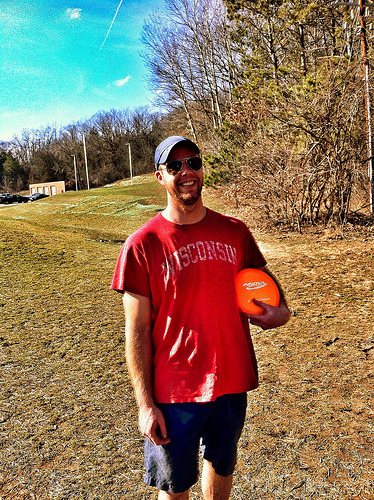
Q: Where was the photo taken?
A: It was taken at the field.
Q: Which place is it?
A: It is a field.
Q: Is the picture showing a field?
A: Yes, it is showing a field.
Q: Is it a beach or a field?
A: It is a field.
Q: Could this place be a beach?
A: No, it is a field.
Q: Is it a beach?
A: No, it is a field.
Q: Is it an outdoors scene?
A: Yes, it is outdoors.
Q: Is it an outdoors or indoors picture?
A: It is outdoors.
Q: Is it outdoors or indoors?
A: It is outdoors.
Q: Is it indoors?
A: No, it is outdoors.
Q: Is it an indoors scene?
A: No, it is outdoors.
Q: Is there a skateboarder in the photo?
A: No, there are no skateboarders.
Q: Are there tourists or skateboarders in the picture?
A: No, there are no skateboarders or tourists.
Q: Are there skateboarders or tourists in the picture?
A: No, there are no skateboarders or tourists.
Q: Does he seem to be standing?
A: Yes, the man is standing.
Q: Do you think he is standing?
A: Yes, the man is standing.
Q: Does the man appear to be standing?
A: Yes, the man is standing.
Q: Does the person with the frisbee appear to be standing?
A: Yes, the man is standing.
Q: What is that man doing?
A: The man is standing.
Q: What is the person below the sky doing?
A: The man is standing.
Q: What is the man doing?
A: The man is standing.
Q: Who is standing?
A: The man is standing.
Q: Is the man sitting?
A: No, the man is standing.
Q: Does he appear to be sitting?
A: No, the man is standing.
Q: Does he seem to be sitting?
A: No, the man is standing.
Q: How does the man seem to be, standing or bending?
A: The man is standing.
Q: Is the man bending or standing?
A: The man is standing.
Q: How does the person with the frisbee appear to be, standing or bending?
A: The man is standing.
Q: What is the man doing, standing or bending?
A: The man is standing.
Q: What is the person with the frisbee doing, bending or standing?
A: The man is standing.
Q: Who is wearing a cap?
A: The man is wearing a cap.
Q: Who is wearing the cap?
A: The man is wearing a cap.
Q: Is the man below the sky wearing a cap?
A: Yes, the man is wearing a cap.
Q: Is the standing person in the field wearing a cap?
A: Yes, the man is wearing a cap.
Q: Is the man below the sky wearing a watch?
A: No, the man is wearing a cap.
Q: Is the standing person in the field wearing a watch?
A: No, the man is wearing a cap.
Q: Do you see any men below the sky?
A: Yes, there is a man below the sky.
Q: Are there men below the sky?
A: Yes, there is a man below the sky.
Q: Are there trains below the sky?
A: No, there is a man below the sky.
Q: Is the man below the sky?
A: Yes, the man is below the sky.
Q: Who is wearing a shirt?
A: The man is wearing a shirt.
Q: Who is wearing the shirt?
A: The man is wearing a shirt.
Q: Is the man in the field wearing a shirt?
A: Yes, the man is wearing a shirt.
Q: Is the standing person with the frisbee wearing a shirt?
A: Yes, the man is wearing a shirt.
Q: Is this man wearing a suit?
A: No, the man is wearing a shirt.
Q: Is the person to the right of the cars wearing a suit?
A: No, the man is wearing a shirt.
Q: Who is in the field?
A: The man is in the field.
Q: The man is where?
A: The man is in the field.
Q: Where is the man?
A: The man is in the field.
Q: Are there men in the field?
A: Yes, there is a man in the field.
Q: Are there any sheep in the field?
A: No, there is a man in the field.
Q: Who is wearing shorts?
A: The man is wearing shorts.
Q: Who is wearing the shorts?
A: The man is wearing shorts.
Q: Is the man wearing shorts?
A: Yes, the man is wearing shorts.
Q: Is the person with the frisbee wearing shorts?
A: Yes, the man is wearing shorts.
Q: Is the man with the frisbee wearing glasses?
A: No, the man is wearing shorts.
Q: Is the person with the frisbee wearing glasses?
A: No, the man is wearing shorts.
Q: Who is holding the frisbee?
A: The man is holding the frisbee.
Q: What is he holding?
A: The man is holding the frisbee.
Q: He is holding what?
A: The man is holding the frisbee.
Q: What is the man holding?
A: The man is holding the frisbee.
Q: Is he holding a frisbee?
A: Yes, the man is holding a frisbee.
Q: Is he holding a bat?
A: No, the man is holding a frisbee.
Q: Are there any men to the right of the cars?
A: Yes, there is a man to the right of the cars.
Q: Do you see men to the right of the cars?
A: Yes, there is a man to the right of the cars.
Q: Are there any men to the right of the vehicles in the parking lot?
A: Yes, there is a man to the right of the cars.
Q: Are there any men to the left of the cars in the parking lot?
A: No, the man is to the right of the cars.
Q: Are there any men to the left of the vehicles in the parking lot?
A: No, the man is to the right of the cars.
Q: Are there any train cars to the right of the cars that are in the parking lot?
A: No, there is a man to the right of the cars.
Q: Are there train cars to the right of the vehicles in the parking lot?
A: No, there is a man to the right of the cars.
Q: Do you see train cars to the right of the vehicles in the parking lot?
A: No, there is a man to the right of the cars.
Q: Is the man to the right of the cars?
A: Yes, the man is to the right of the cars.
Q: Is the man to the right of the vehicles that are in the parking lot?
A: Yes, the man is to the right of the cars.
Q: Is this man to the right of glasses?
A: No, the man is to the right of the cars.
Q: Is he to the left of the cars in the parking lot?
A: No, the man is to the right of the cars.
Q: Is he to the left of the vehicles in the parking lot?
A: No, the man is to the right of the cars.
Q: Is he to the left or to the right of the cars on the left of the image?
A: The man is to the right of the cars.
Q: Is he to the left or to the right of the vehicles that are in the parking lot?
A: The man is to the right of the cars.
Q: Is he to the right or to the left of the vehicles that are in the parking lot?
A: The man is to the right of the cars.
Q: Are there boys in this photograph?
A: No, there are no boys.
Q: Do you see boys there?
A: No, there are no boys.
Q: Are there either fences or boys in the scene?
A: No, there are no boys or fences.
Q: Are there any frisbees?
A: Yes, there is a frisbee.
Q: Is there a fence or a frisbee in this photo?
A: Yes, there is a frisbee.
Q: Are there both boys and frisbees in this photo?
A: No, there is a frisbee but no boys.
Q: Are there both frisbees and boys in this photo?
A: No, there is a frisbee but no boys.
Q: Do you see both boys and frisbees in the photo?
A: No, there is a frisbee but no boys.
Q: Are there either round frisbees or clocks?
A: Yes, there is a round frisbee.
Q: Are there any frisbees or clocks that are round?
A: Yes, the frisbee is round.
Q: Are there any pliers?
A: No, there are no pliers.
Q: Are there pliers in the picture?
A: No, there are no pliers.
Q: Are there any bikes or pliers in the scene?
A: No, there are no pliers or bikes.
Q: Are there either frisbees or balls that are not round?
A: No, there is a frisbee but it is round.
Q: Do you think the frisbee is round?
A: Yes, the frisbee is round.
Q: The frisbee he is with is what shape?
A: The frisbee is round.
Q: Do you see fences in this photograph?
A: No, there are no fences.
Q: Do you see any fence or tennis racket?
A: No, there are no fences or rackets.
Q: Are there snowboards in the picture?
A: No, there are no snowboards.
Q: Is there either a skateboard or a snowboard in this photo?
A: No, there are no snowboards or skateboards.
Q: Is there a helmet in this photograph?
A: No, there are no helmets.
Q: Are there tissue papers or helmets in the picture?
A: No, there are no helmets or tissue papers.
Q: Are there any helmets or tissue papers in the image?
A: No, there are no helmets or tissue papers.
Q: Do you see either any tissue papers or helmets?
A: No, there are no helmets or tissue papers.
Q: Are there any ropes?
A: No, there are no ropes.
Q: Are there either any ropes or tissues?
A: No, there are no ropes or tissues.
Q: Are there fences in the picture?
A: No, there are no fences.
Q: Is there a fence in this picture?
A: No, there are no fences.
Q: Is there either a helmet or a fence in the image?
A: No, there are no fences or helmets.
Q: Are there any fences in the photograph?
A: No, there are no fences.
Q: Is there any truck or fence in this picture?
A: No, there are no fences or trucks.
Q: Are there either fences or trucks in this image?
A: No, there are no fences or trucks.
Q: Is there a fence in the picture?
A: No, there are no fences.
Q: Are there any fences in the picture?
A: No, there are no fences.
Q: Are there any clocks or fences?
A: No, there are no fences or clocks.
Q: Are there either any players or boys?
A: No, there are no boys or players.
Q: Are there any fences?
A: No, there are no fences.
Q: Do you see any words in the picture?
A: Yes, there are words.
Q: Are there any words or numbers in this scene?
A: Yes, there are words.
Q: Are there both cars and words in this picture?
A: Yes, there are both words and a car.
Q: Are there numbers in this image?
A: No, there are no numbers.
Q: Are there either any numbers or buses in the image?
A: No, there are no numbers or buses.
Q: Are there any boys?
A: No, there are no boys.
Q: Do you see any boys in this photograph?
A: No, there are no boys.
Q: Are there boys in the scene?
A: No, there are no boys.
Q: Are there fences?
A: No, there are no fences.